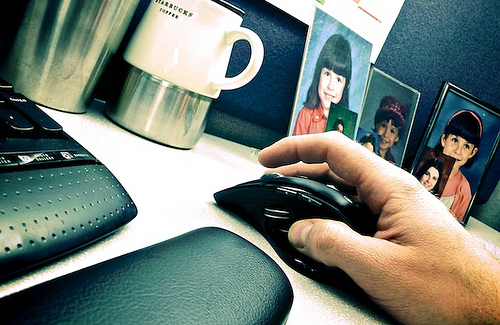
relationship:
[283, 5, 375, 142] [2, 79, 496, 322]
picture on desk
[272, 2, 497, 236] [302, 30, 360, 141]
picture of girl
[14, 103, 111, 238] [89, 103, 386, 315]
keyboard on a desk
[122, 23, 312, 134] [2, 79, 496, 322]
cup on desk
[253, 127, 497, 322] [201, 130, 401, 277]
person holding mouse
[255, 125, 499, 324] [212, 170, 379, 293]
person´s hand holding mouse